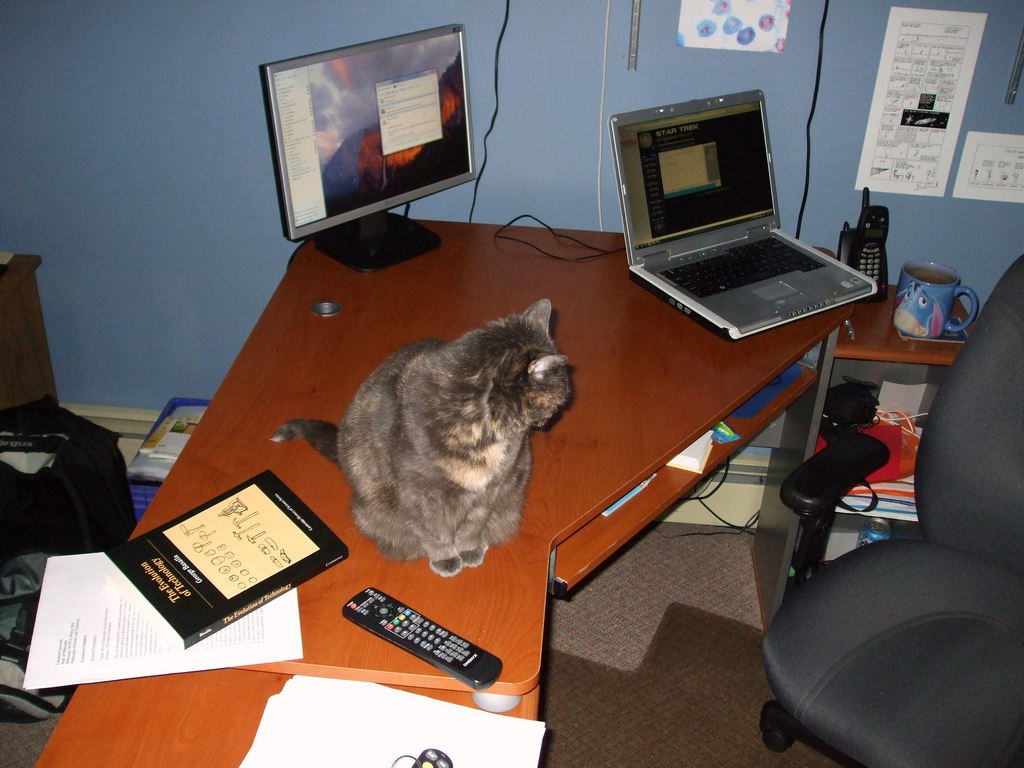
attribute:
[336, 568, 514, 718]
control — remote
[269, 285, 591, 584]
cat — brown, greyish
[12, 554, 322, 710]
papers — some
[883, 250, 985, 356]
mug — blue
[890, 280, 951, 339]
eeyore — picture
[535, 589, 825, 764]
mat — plastic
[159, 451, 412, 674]
book — cream, black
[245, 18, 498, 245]
screen — LCD, computer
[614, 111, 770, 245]
screen — computer, laptop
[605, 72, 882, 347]
laptop — large , grey 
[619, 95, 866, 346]
computer — laptop, thick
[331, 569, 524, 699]
control — black, remote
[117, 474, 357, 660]
book — small, black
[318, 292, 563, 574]
cat — one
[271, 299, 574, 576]
cat — grey , large 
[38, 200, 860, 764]
desk — brown , large 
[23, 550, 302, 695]
paper — large , white 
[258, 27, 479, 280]
monitor — large 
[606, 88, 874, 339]
laptop — grey 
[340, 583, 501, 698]
controller — large , black 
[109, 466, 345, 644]
book — large , black 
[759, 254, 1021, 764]
chair — grey , large 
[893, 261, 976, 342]
cup — blue , ceramic , small 